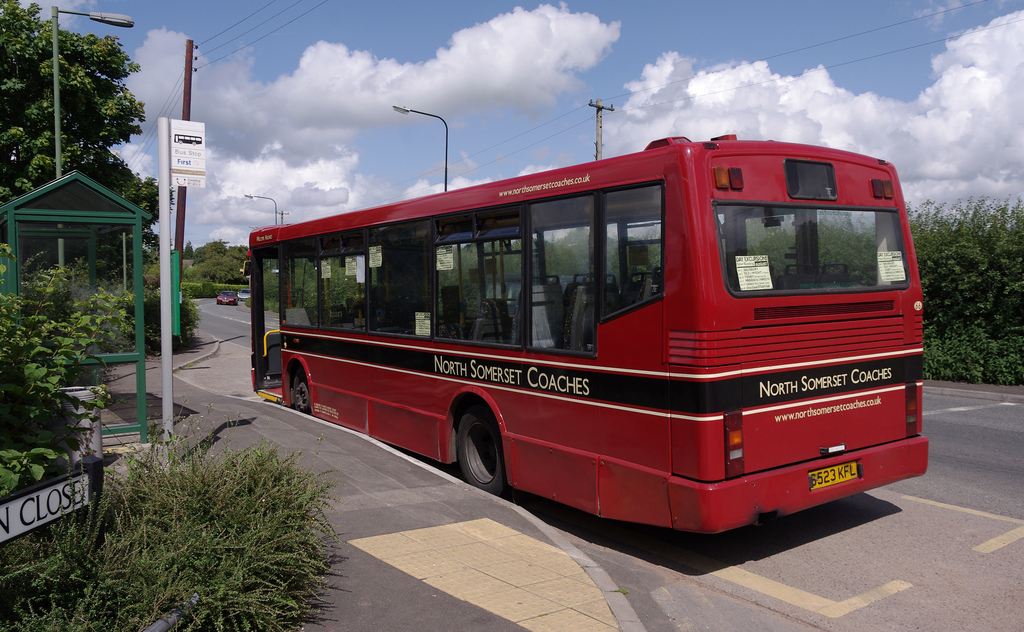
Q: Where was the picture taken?
A: At a bus stop.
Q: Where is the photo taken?
A: On the street.